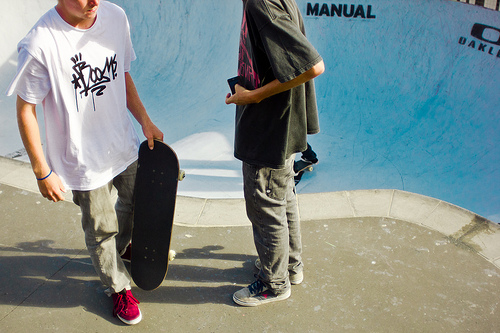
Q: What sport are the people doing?
A: Skateboarding.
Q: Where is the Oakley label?
A: On skate bowl.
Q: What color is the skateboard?
A: Black.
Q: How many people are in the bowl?
A: 1.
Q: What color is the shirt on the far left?
A: White.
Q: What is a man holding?
A: Skateboard.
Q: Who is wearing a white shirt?
A: Person on left.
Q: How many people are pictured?
A: Two.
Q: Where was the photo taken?
A: At a skateboard park.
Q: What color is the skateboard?
A: Black.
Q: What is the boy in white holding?
A: Skateboard.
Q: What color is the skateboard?
A: Black.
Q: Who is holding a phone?
A: The guy n a black shirt.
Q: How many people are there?
A: Two.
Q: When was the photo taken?
A: In the daytime.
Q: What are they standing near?
A: A skate park.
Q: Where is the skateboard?
A: In his hand.